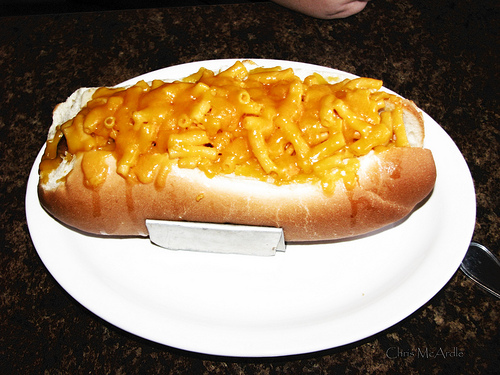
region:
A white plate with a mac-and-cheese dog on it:
[19, 27, 482, 364]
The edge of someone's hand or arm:
[241, 0, 406, 26]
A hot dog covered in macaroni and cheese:
[34, 84, 434, 238]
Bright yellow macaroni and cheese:
[99, 80, 370, 155]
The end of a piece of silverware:
[458, 232, 498, 286]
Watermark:
[381, 339, 473, 366]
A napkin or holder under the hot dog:
[141, 211, 298, 261]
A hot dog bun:
[50, 155, 443, 232]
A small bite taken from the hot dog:
[28, 76, 115, 222]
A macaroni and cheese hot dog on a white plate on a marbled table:
[30, 53, 484, 351]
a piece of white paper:
[141, 213, 292, 260]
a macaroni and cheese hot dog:
[26, 56, 436, 248]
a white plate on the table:
[26, 51, 480, 363]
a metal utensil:
[457, 234, 498, 293]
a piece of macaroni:
[239, 119, 276, 176]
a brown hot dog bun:
[31, 143, 443, 240]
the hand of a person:
[269, 0, 371, 25]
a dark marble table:
[0, 0, 498, 373]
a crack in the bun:
[296, 189, 316, 244]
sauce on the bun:
[85, 183, 107, 222]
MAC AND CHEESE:
[219, 79, 336, 164]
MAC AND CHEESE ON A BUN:
[41, 56, 438, 257]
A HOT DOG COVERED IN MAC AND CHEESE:
[28, 62, 439, 253]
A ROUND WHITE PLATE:
[16, 59, 484, 368]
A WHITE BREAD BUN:
[36, 62, 450, 248]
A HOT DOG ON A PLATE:
[14, 36, 487, 368]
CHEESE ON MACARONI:
[80, 85, 265, 155]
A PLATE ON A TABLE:
[11, 30, 476, 365]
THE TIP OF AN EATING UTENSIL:
[453, 222, 495, 312]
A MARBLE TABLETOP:
[16, 21, 130, 81]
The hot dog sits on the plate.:
[79, 56, 439, 339]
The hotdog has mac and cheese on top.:
[66, 81, 441, 245]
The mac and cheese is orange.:
[103, 80, 344, 160]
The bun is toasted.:
[55, 175, 388, 228]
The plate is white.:
[36, 201, 449, 353]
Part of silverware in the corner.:
[458, 231, 498, 303]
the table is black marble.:
[11, 228, 498, 363]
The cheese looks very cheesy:
[136, 92, 336, 162]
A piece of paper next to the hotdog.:
[131, 214, 308, 311]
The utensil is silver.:
[458, 236, 493, 293]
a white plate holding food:
[35, 51, 473, 358]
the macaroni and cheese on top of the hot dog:
[56, 62, 406, 184]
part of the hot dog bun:
[46, 155, 430, 232]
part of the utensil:
[460, 243, 499, 287]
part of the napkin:
[287, 0, 366, 21]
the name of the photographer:
[378, 346, 467, 362]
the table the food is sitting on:
[8, 3, 496, 371]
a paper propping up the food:
[139, 221, 291, 264]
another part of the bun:
[392, 95, 422, 145]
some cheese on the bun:
[242, 160, 271, 178]